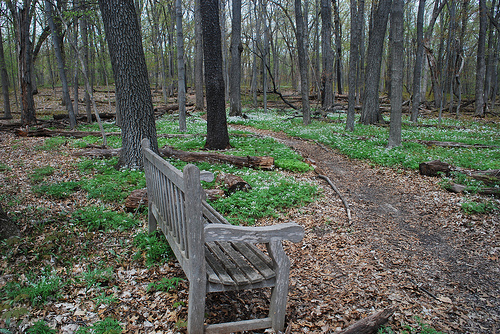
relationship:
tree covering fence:
[387, 8, 406, 145] [67, 84, 387, 176]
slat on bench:
[211, 253, 281, 287] [133, 137, 309, 332]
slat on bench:
[184, 208, 244, 269] [133, 137, 309, 332]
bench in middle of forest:
[141, 137, 304, 333] [49, 5, 483, 321]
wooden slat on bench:
[165, 185, 180, 246] [133, 137, 309, 332]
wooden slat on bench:
[209, 245, 271, 283] [133, 137, 309, 332]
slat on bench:
[205, 260, 219, 285] [133, 137, 309, 332]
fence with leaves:
[0, 87, 498, 122] [113, 265, 147, 295]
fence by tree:
[0, 87, 498, 122] [94, 0, 162, 172]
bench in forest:
[133, 137, 309, 332] [0, 0, 497, 332]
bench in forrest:
[141, 137, 304, 333] [0, 0, 498, 328]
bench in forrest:
[141, 137, 304, 333] [65, 8, 480, 155]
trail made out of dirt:
[227, 120, 497, 329] [235, 120, 498, 329]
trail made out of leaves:
[227, 120, 497, 329] [287, 133, 497, 331]